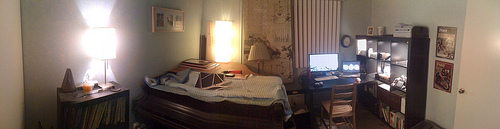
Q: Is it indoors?
A: Yes, it is indoors.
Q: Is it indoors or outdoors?
A: It is indoors.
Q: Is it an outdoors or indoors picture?
A: It is indoors.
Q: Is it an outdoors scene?
A: No, it is indoors.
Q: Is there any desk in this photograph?
A: Yes, there is a desk.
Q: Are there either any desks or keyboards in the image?
A: Yes, there is a desk.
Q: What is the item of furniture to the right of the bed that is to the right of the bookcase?
A: The piece of furniture is a desk.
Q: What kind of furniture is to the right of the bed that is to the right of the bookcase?
A: The piece of furniture is a desk.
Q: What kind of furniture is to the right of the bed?
A: The piece of furniture is a desk.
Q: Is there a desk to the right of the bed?
A: Yes, there is a desk to the right of the bed.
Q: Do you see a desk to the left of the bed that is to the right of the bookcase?
A: No, the desk is to the right of the bed.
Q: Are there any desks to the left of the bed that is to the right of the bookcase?
A: No, the desk is to the right of the bed.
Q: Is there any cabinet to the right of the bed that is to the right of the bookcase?
A: No, there is a desk to the right of the bed.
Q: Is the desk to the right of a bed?
A: Yes, the desk is to the right of a bed.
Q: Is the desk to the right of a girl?
A: No, the desk is to the right of a bed.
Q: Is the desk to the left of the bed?
A: No, the desk is to the right of the bed.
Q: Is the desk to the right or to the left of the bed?
A: The desk is to the right of the bed.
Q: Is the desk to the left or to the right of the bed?
A: The desk is to the right of the bed.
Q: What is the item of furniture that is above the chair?
A: The piece of furniture is a desk.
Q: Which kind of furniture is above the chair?
A: The piece of furniture is a desk.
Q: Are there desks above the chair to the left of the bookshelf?
A: Yes, there is a desk above the chair.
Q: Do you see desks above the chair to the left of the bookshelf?
A: Yes, there is a desk above the chair.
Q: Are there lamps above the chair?
A: No, there is a desk above the chair.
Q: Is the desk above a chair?
A: Yes, the desk is above a chair.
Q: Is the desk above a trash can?
A: No, the desk is above a chair.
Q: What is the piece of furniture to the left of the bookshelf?
A: The piece of furniture is a desk.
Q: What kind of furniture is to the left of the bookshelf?
A: The piece of furniture is a desk.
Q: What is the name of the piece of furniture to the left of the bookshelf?
A: The piece of furniture is a desk.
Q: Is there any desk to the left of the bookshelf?
A: Yes, there is a desk to the left of the bookshelf.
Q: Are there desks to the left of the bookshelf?
A: Yes, there is a desk to the left of the bookshelf.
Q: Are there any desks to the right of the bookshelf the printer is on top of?
A: No, the desk is to the left of the bookshelf.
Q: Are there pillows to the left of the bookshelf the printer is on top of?
A: No, there is a desk to the left of the bookshelf.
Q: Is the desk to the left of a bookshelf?
A: Yes, the desk is to the left of a bookshelf.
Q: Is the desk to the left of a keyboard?
A: No, the desk is to the left of a bookshelf.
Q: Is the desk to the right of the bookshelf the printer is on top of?
A: No, the desk is to the left of the bookshelf.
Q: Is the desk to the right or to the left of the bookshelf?
A: The desk is to the left of the bookshelf.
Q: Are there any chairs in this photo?
A: Yes, there is a chair.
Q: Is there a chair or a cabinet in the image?
A: Yes, there is a chair.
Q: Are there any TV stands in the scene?
A: No, there are no TV stands.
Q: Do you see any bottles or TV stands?
A: No, there are no TV stands or bottles.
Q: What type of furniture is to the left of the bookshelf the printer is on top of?
A: The piece of furniture is a chair.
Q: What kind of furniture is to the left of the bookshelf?
A: The piece of furniture is a chair.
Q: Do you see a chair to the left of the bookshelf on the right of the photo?
A: Yes, there is a chair to the left of the bookshelf.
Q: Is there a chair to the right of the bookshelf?
A: No, the chair is to the left of the bookshelf.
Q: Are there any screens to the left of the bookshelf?
A: No, there is a chair to the left of the bookshelf.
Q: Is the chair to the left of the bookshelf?
A: Yes, the chair is to the left of the bookshelf.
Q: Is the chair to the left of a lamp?
A: No, the chair is to the left of the bookshelf.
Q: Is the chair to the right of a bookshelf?
A: No, the chair is to the left of a bookshelf.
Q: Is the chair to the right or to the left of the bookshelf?
A: The chair is to the left of the bookshelf.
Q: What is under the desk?
A: The chair is under the desk.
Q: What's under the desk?
A: The chair is under the desk.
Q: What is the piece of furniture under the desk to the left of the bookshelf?
A: The piece of furniture is a chair.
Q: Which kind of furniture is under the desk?
A: The piece of furniture is a chair.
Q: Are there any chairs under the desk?
A: Yes, there is a chair under the desk.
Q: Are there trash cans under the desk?
A: No, there is a chair under the desk.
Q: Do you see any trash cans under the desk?
A: No, there is a chair under the desk.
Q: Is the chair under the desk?
A: Yes, the chair is under the desk.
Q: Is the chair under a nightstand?
A: No, the chair is under the desk.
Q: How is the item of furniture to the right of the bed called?
A: The piece of furniture is a chair.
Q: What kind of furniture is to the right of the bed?
A: The piece of furniture is a chair.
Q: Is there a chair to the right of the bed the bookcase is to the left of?
A: Yes, there is a chair to the right of the bed.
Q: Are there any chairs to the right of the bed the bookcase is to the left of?
A: Yes, there is a chair to the right of the bed.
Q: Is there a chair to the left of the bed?
A: No, the chair is to the right of the bed.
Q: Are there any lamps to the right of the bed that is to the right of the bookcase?
A: No, there is a chair to the right of the bed.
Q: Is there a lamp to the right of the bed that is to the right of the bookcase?
A: No, there is a chair to the right of the bed.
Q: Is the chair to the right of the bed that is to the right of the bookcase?
A: Yes, the chair is to the right of the bed.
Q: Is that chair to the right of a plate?
A: No, the chair is to the right of the bed.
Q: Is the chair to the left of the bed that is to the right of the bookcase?
A: No, the chair is to the right of the bed.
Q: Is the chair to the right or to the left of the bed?
A: The chair is to the right of the bed.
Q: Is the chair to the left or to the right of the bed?
A: The chair is to the right of the bed.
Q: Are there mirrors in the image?
A: No, there are no mirrors.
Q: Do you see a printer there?
A: Yes, there is a printer.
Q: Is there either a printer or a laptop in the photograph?
A: Yes, there is a printer.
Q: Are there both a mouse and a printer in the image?
A: No, there is a printer but no computer mice.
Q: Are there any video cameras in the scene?
A: No, there are no video cameras.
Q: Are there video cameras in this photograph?
A: No, there are no video cameras.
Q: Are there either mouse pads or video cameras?
A: No, there are no video cameras or mouse pads.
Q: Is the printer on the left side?
A: No, the printer is on the right of the image.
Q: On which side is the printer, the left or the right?
A: The printer is on the right of the image.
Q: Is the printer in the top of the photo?
A: Yes, the printer is in the top of the image.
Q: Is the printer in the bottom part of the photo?
A: No, the printer is in the top of the image.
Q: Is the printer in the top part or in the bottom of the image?
A: The printer is in the top of the image.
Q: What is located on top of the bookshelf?
A: The printer is on top of the bookshelf.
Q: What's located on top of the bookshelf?
A: The printer is on top of the bookshelf.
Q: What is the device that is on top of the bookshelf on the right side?
A: The device is a printer.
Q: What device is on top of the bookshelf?
A: The device is a printer.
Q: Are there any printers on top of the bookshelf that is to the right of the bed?
A: Yes, there is a printer on top of the bookshelf.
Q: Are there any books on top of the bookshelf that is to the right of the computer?
A: No, there is a printer on top of the bookshelf.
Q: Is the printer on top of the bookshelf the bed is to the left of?
A: Yes, the printer is on top of the bookshelf.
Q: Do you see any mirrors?
A: No, there are no mirrors.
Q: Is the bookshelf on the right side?
A: Yes, the bookshelf is on the right of the image.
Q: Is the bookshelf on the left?
A: No, the bookshelf is on the right of the image.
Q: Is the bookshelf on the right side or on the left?
A: The bookshelf is on the right of the image.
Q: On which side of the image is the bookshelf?
A: The bookshelf is on the right of the image.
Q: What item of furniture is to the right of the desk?
A: The piece of furniture is a bookshelf.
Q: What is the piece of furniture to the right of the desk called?
A: The piece of furniture is a bookshelf.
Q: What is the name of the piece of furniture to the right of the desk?
A: The piece of furniture is a bookshelf.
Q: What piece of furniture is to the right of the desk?
A: The piece of furniture is a bookshelf.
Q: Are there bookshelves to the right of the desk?
A: Yes, there is a bookshelf to the right of the desk.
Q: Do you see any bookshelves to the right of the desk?
A: Yes, there is a bookshelf to the right of the desk.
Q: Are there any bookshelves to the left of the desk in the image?
A: No, the bookshelf is to the right of the desk.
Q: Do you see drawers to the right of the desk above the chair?
A: No, there is a bookshelf to the right of the desk.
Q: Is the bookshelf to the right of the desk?
A: Yes, the bookshelf is to the right of the desk.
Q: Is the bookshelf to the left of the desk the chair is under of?
A: No, the bookshelf is to the right of the desk.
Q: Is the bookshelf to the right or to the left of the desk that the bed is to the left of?
A: The bookshelf is to the right of the desk.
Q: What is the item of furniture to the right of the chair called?
A: The piece of furniture is a bookshelf.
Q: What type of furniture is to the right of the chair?
A: The piece of furniture is a bookshelf.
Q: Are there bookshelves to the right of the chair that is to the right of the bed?
A: Yes, there is a bookshelf to the right of the chair.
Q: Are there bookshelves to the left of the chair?
A: No, the bookshelf is to the right of the chair.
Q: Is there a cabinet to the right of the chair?
A: No, there is a bookshelf to the right of the chair.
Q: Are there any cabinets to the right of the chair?
A: No, there is a bookshelf to the right of the chair.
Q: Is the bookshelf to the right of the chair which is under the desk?
A: Yes, the bookshelf is to the right of the chair.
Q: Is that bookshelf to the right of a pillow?
A: No, the bookshelf is to the right of the chair.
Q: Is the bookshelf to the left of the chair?
A: No, the bookshelf is to the right of the chair.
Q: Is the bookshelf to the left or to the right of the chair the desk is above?
A: The bookshelf is to the right of the chair.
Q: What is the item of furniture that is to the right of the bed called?
A: The piece of furniture is a bookshelf.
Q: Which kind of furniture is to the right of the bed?
A: The piece of furniture is a bookshelf.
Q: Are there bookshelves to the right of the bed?
A: Yes, there is a bookshelf to the right of the bed.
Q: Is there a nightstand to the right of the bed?
A: No, there is a bookshelf to the right of the bed.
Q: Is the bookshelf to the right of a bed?
A: Yes, the bookshelf is to the right of a bed.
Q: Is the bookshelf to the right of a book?
A: No, the bookshelf is to the right of a bed.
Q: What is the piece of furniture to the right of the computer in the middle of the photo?
A: The piece of furniture is a bookshelf.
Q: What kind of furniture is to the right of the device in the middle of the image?
A: The piece of furniture is a bookshelf.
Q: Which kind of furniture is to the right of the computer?
A: The piece of furniture is a bookshelf.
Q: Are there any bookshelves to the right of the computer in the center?
A: Yes, there is a bookshelf to the right of the computer.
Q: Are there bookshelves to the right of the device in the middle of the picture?
A: Yes, there is a bookshelf to the right of the computer.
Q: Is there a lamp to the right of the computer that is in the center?
A: No, there is a bookshelf to the right of the computer.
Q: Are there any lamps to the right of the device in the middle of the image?
A: No, there is a bookshelf to the right of the computer.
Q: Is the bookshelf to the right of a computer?
A: Yes, the bookshelf is to the right of a computer.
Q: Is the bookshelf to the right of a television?
A: No, the bookshelf is to the right of a computer.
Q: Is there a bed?
A: Yes, there is a bed.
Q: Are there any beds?
A: Yes, there is a bed.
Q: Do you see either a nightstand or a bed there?
A: Yes, there is a bed.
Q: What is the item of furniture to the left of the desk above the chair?
A: The piece of furniture is a bed.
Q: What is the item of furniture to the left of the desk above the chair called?
A: The piece of furniture is a bed.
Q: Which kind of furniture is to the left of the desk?
A: The piece of furniture is a bed.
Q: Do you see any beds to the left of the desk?
A: Yes, there is a bed to the left of the desk.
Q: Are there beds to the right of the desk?
A: No, the bed is to the left of the desk.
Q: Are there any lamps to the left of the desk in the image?
A: No, there is a bed to the left of the desk.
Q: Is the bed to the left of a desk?
A: Yes, the bed is to the left of a desk.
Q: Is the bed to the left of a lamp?
A: No, the bed is to the left of a desk.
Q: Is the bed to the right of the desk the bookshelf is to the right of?
A: No, the bed is to the left of the desk.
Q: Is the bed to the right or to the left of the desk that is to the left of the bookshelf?
A: The bed is to the left of the desk.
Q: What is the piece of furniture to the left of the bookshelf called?
A: The piece of furniture is a bed.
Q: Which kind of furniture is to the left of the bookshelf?
A: The piece of furniture is a bed.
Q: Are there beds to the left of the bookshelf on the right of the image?
A: Yes, there is a bed to the left of the bookshelf.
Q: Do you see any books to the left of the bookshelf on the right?
A: No, there is a bed to the left of the bookshelf.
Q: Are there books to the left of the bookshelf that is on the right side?
A: No, there is a bed to the left of the bookshelf.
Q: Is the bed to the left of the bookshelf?
A: Yes, the bed is to the left of the bookshelf.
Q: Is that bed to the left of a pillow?
A: No, the bed is to the left of the bookshelf.